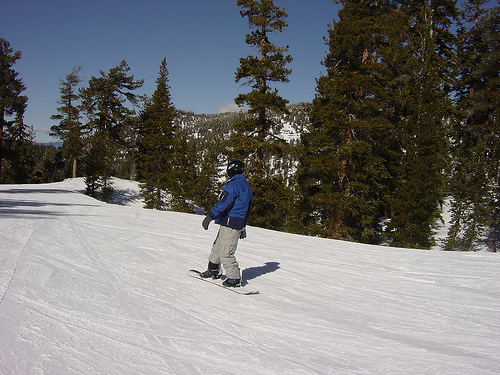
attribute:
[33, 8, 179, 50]
sky — blue, clear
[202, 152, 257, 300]
person — skiing, snowboarding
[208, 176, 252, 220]
jacket — blue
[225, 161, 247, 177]
helmet — black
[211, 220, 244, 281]
pants — gray, grey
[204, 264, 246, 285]
boots — black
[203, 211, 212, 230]
gloves — black, grey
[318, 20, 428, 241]
trees — lush, abundunt, tall, green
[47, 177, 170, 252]
slope — white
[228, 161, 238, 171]
emblem — white